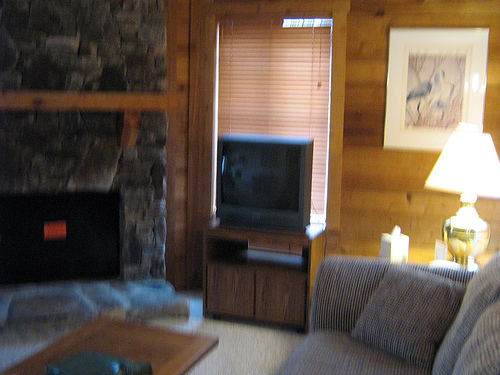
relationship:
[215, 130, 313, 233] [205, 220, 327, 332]
tv on top of stand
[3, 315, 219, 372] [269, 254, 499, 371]
table in front of couch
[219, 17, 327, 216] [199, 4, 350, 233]
blinds cover window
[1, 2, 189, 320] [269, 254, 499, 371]
fireplace opposite couch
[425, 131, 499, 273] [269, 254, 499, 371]
lamp next to couch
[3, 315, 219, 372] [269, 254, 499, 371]
table next to couch